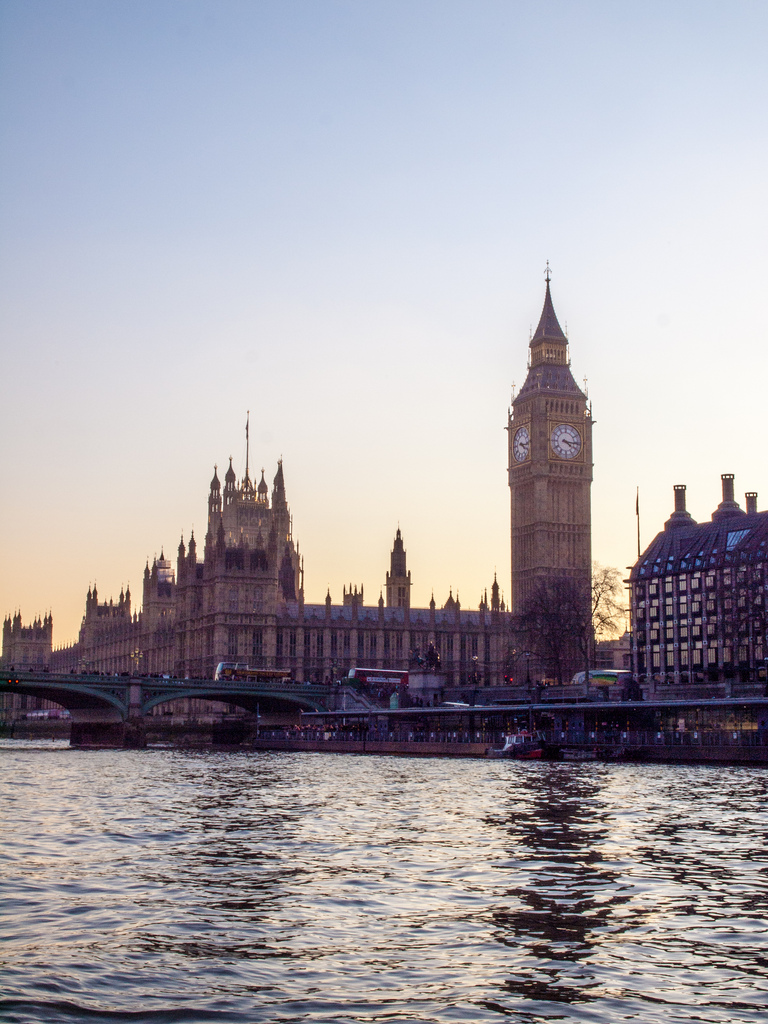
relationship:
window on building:
[674, 561, 708, 614] [628, 471, 760, 691]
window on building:
[658, 573, 671, 591] [628, 471, 760, 691]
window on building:
[633, 594, 646, 618] [628, 471, 760, 691]